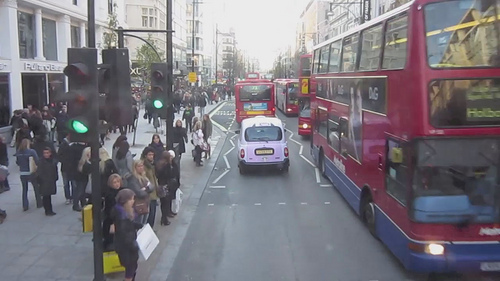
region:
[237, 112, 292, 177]
A car painted pink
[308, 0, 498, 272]
A red double decker bus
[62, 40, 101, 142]
A stoplight with green light illuminated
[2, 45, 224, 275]
Busy city sidewalk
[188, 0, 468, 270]
City street with double decker buses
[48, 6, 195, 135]
Three traffic lights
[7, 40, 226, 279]
Pedestrians on sidewalk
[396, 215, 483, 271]
The headlight on the bus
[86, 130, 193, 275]
Pedestrians waiting to cross the street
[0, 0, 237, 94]
Tall buildings along city street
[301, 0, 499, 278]
Double decker bus is red.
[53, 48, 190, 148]
Two streetlights are green.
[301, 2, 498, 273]
Double decker bus has headlights on.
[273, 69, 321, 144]
Two buses are behind double decker bus.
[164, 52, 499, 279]
Traffic going both ways on two lane street.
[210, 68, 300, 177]
White car is following bus.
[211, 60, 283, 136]
Red bus in front of white car.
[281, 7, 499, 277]
Three buses in right lane have headlights on.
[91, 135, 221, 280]
People waiting on sidewalk to cross street.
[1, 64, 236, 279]
Lots of people walking on the sidewak.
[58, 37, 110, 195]
a traffic signal on a pole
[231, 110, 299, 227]
a vehicle on a street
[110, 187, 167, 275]
a person holding a white bag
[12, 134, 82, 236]
people standing on a sidewalk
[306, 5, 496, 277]
a doubledecker bus on a street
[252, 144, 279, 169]
a licence plate on the back of a car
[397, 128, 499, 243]
the front windshield of a bus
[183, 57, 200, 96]
a yellow sign on a pole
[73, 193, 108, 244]
a yellow box attached to a pole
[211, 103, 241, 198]
white markings on a street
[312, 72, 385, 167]
dolce & gabbana ad on side of new red doubledecker bus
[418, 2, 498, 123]
buildings reflected in front window of new red doubledecker bus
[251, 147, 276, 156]
buttercup yellow european license plate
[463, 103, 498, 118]
'Holbo' [probably for holborn] destination notation front of bus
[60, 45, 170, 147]
all lights are green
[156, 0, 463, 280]
heavily trafficked high street in london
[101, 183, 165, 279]
woman with blonde hair+lavender scarf carries white store shopping bag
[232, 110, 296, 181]
little white english car with vertical oblong taillights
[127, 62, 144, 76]
letters 'xt' on sign in the left high mid-ground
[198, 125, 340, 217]
jaggedy markings before evenly spaced rectangular markings, all white, on street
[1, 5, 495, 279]
Street of a city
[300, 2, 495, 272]
Red double decker bus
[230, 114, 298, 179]
White car behind red bus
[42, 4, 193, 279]
three traffic lights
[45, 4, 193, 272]
Traffic lights are in green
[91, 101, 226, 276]
People standing on border of sidewalk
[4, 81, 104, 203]
People walking on sidewalk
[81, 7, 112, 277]
Pole of traffic light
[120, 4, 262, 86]
Tall building in the city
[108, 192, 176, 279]
Woman holding a white bag